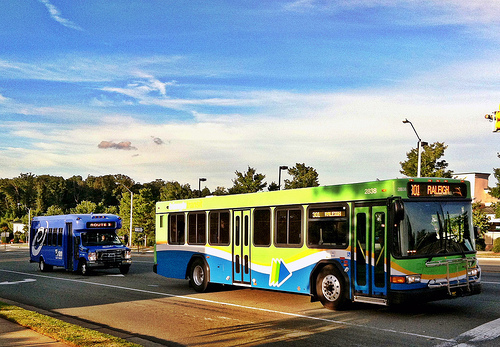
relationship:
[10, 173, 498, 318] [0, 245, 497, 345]
bus driving on street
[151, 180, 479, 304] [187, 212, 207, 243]
bus has window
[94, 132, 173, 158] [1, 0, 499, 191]
clouds in sky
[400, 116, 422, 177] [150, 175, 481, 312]
street lamp behind bus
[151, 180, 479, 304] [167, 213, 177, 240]
bus has window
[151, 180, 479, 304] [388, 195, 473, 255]
bus has window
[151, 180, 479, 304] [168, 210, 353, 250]
bus has window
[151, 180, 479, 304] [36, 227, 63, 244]
bus has window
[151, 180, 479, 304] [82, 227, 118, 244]
bus has window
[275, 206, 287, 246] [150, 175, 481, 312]
window on bus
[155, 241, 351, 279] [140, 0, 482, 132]
white swirl on side of bus